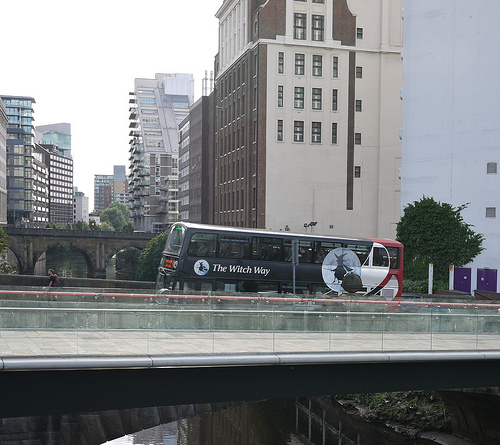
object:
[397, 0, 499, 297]
building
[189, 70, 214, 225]
building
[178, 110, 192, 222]
building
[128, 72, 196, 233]
building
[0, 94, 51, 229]
building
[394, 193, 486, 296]
tree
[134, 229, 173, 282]
tree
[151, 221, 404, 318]
bus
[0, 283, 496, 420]
bridge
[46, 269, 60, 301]
man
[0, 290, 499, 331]
street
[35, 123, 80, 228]
building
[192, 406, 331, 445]
water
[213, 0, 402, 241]
building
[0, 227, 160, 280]
bridge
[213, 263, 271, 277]
print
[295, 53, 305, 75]
window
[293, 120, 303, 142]
window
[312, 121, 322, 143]
window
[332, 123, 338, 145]
window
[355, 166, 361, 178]
window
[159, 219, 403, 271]
top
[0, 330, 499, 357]
road